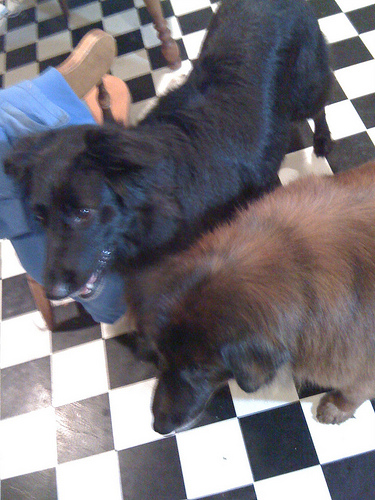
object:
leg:
[138, 1, 193, 77]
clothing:
[5, 68, 116, 288]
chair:
[3, 25, 137, 335]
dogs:
[116, 159, 375, 437]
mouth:
[70, 265, 97, 299]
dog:
[11, 5, 315, 342]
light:
[83, 211, 86, 212]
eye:
[68, 203, 92, 223]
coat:
[166, 27, 284, 185]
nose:
[42, 282, 73, 302]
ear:
[80, 123, 168, 211]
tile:
[45, 393, 120, 462]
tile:
[49, 337, 112, 411]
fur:
[138, 27, 256, 150]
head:
[5, 118, 155, 307]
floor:
[2, 0, 373, 498]